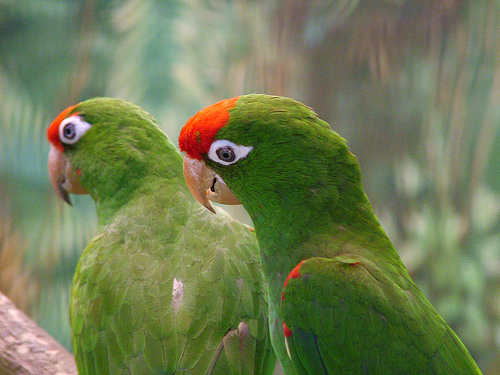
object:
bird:
[178, 91, 483, 375]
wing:
[280, 252, 449, 374]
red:
[282, 257, 304, 338]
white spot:
[173, 277, 183, 313]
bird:
[45, 95, 275, 374]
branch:
[0, 292, 74, 375]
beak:
[183, 156, 243, 214]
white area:
[207, 139, 254, 166]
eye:
[215, 146, 235, 162]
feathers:
[245, 156, 435, 374]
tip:
[205, 202, 217, 214]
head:
[46, 96, 184, 214]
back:
[337, 197, 480, 373]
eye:
[63, 123, 77, 139]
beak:
[47, 143, 89, 206]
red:
[46, 101, 74, 155]